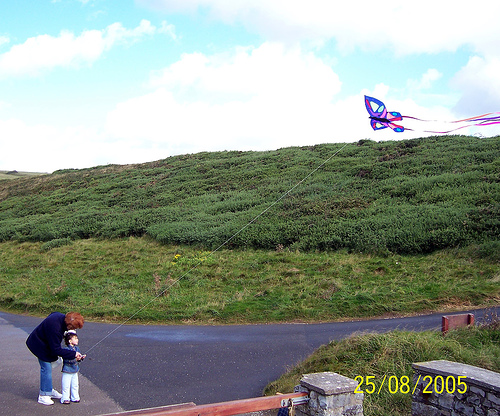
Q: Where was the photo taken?
A: It was taken at the field.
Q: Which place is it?
A: It is a field.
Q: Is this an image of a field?
A: Yes, it is showing a field.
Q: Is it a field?
A: Yes, it is a field.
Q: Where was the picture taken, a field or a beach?
A: It was taken at a field.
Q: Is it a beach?
A: No, it is a field.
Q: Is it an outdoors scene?
A: Yes, it is outdoors.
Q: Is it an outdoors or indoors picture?
A: It is outdoors.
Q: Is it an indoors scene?
A: No, it is outdoors.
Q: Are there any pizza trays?
A: No, there are no pizza trays.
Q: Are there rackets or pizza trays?
A: No, there are no pizza trays or rackets.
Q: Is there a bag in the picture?
A: No, there are no bags.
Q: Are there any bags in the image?
A: No, there are no bags.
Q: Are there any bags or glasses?
A: No, there are no bags or glasses.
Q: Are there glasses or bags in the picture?
A: No, there are no bags or glasses.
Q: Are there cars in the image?
A: No, there are no cars.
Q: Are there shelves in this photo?
A: No, there are no shelves.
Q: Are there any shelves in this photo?
A: No, there are no shelves.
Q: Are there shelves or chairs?
A: No, there are no shelves or chairs.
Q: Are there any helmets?
A: No, there are no helmets.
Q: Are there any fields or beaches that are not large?
A: No, there is a field but it is large.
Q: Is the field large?
A: Yes, the field is large.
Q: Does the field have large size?
A: Yes, the field is large.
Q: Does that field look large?
A: Yes, the field is large.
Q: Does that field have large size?
A: Yes, the field is large.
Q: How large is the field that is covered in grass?
A: The field is large.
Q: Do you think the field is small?
A: No, the field is large.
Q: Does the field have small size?
A: No, the field is large.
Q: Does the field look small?
A: No, the field is large.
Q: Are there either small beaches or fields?
A: No, there is a field but it is large.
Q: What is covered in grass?
A: The field is covered in grass.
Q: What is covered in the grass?
A: The field is covered in grass.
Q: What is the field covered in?
A: The field is covered in grass.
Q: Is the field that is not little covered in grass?
A: Yes, the field is covered in grass.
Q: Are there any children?
A: Yes, there is a child.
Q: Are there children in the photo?
A: Yes, there is a child.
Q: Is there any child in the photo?
A: Yes, there is a child.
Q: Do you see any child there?
A: Yes, there is a child.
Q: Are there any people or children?
A: Yes, there is a child.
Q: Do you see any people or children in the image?
A: Yes, there is a child.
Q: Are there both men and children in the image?
A: No, there is a child but no men.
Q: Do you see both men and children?
A: No, there is a child but no men.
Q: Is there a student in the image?
A: No, there are no students.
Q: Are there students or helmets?
A: No, there are no students or helmets.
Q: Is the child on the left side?
A: Yes, the child is on the left of the image.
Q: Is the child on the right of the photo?
A: No, the child is on the left of the image.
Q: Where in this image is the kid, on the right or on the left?
A: The kid is on the left of the image.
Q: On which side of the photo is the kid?
A: The kid is on the left of the image.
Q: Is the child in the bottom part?
A: Yes, the child is in the bottom of the image.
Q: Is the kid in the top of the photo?
A: No, the kid is in the bottom of the image.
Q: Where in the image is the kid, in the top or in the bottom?
A: The kid is in the bottom of the image.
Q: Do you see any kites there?
A: Yes, there is a kite.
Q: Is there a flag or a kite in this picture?
A: Yes, there is a kite.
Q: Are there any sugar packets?
A: No, there are no sugar packets.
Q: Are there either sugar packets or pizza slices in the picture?
A: No, there are no sugar packets or pizza slices.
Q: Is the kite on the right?
A: Yes, the kite is on the right of the image.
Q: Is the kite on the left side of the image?
A: No, the kite is on the right of the image.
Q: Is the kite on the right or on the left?
A: The kite is on the right of the image.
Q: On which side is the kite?
A: The kite is on the right of the image.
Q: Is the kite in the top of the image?
A: Yes, the kite is in the top of the image.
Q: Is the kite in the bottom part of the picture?
A: No, the kite is in the top of the image.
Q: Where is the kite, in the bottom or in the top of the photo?
A: The kite is in the top of the image.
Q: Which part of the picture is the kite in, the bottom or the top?
A: The kite is in the top of the image.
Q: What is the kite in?
A: The kite is in the air.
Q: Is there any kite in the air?
A: Yes, there is a kite in the air.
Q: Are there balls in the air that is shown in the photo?
A: No, there is a kite in the air.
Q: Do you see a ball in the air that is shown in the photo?
A: No, there is a kite in the air.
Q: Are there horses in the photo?
A: No, there are no horses.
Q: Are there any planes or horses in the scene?
A: No, there are no horses or planes.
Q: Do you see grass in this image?
A: Yes, there is grass.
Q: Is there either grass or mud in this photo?
A: Yes, there is grass.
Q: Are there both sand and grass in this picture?
A: No, there is grass but no sand.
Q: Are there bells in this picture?
A: No, there are no bells.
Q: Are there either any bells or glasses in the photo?
A: No, there are no bells or glasses.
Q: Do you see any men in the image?
A: No, there are no men.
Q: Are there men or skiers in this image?
A: No, there are no men or skiers.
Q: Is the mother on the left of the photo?
A: Yes, the mother is on the left of the image.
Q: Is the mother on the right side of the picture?
A: No, the mother is on the left of the image.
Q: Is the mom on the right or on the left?
A: The mom is on the left of the image.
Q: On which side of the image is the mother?
A: The mother is on the left of the image.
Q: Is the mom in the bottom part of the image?
A: Yes, the mom is in the bottom of the image.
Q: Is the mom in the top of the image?
A: No, the mom is in the bottom of the image.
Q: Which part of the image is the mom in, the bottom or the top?
A: The mom is in the bottom of the image.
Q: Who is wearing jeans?
A: The mom is wearing jeans.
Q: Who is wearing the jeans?
A: The mom is wearing jeans.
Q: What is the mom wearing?
A: The mom is wearing jeans.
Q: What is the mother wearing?
A: The mom is wearing jeans.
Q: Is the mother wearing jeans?
A: Yes, the mother is wearing jeans.